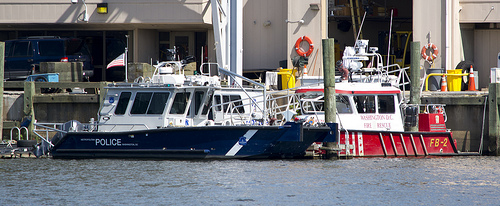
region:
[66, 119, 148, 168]
white writing on boat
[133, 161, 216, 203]
water next to boat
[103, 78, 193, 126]
windows on the boat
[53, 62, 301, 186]
blue and white boat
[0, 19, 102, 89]
car near the boat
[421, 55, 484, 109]
orange cones in photo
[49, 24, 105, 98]
back of a car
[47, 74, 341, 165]
a blue police boat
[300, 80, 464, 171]
a yellow boat in the water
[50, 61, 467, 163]
two boats parked at the dock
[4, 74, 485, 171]
a boardwalk by the ocean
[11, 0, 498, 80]
buildings along a pier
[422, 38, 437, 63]
a life jacket pinned to a wall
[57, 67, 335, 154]
a police boat parked by the sea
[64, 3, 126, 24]
a light on a stone wall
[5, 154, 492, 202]
a slow flowing section of the ocean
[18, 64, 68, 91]
a blue bucket on the dock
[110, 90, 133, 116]
window on side of boat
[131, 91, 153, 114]
window on side of boat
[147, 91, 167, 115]
window on side of boat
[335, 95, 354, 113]
window on side of boat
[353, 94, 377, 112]
window on side of boat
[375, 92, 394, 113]
window on side of boat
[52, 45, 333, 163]
police boat is white and blue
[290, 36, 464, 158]
red and white boat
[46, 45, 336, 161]
blue and white boat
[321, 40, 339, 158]
brown pole sticking out of water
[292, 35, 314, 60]
circular orange life preserve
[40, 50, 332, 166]
white and blue police boat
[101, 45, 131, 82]
american flag on a metal pole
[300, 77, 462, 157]
red and white boat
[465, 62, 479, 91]
orange and white traffic cone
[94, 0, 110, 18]
black light fixture with yellow light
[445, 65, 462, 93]
large lidless yellow garbage can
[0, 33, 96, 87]
dark blue vehicle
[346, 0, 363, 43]
tall yellow metal ladder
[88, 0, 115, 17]
a light on a building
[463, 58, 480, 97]
a cone on the pier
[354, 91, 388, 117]
a window on a boat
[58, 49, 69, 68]
a light on a car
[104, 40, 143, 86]
a flag on a pole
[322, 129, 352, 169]
a pole in the water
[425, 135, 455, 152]
letters on the boat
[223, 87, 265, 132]
rails on the boat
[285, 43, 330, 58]
a saftey ring on the wall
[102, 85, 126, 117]
a light on the boat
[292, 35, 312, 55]
The circle preserver mounted on the left of the building.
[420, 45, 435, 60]
The circle preserver mounted on the right side of the building.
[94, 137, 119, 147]
The word Police on the boat.